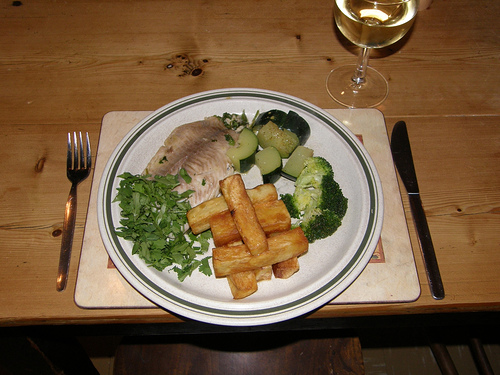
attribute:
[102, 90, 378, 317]
stripe — green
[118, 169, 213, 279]
cilantro — Finely chopped, wilted 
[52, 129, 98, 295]
fork — steel, silverware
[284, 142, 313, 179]
zucchini — sliced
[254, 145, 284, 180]
zucchini — sliced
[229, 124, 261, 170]
zucchini — sliced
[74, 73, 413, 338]
plate — white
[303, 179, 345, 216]
broccoli — green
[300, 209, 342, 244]
broccoli — green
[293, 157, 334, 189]
broccoli — green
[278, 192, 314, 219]
broccoli — green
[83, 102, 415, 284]
mat — rectangular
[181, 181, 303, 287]
sliced potatoes — stack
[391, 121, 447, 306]
knife — scuffed, silver, metal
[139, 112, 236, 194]
fish fillet — baked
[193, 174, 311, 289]
fries — golden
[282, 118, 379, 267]
broccoli — cooked, green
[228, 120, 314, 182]
coocked zucchini — chunks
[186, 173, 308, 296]
potatoes — cut , french fried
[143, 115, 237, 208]
fish — baked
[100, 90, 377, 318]
rim — green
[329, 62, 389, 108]
bottom — clear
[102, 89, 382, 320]
ring — green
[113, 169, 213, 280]
parsley — chopped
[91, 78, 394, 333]
plate — white